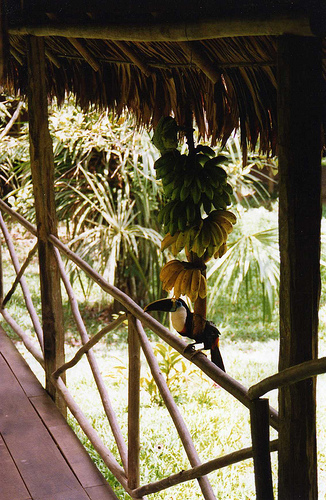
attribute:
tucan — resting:
[141, 298, 234, 353]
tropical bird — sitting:
[136, 284, 244, 384]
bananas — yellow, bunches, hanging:
[148, 132, 235, 311]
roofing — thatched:
[6, 5, 325, 125]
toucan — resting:
[140, 294, 228, 375]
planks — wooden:
[0, 320, 121, 497]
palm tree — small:
[232, 225, 278, 280]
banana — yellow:
[160, 256, 175, 278]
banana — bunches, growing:
[186, 181, 203, 209]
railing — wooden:
[3, 195, 293, 496]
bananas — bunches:
[139, 121, 238, 305]